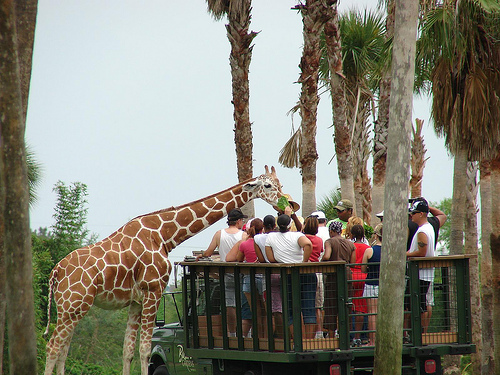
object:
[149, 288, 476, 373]
truck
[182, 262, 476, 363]
back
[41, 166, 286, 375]
giraffe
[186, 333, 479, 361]
platform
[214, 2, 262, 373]
trees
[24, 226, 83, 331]
brush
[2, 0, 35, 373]
tree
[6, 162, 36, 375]
trunk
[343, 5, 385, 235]
tree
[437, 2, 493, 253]
tree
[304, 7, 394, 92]
palm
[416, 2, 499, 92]
palm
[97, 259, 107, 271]
spots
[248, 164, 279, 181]
top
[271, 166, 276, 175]
ossicone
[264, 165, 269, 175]
ossicones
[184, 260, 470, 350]
fence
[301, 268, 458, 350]
grid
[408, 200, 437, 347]
man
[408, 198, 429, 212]
cap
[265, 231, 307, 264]
shirt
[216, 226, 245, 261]
shirt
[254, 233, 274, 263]
shirt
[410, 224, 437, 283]
shirt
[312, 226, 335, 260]
shirt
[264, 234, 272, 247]
sleeves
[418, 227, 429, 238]
sleeves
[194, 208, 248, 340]
people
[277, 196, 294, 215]
food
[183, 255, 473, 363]
wagon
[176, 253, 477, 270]
railing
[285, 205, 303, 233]
person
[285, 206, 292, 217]
hand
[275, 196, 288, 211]
leaf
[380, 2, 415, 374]
tree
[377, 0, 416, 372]
bark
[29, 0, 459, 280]
sky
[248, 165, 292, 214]
head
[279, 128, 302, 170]
leaf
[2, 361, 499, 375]
down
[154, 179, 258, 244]
neck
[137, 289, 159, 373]
legs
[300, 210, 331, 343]
person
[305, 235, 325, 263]
shirt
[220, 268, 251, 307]
shorts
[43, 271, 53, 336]
tail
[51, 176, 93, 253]
tree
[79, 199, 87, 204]
leaves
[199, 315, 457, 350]
deck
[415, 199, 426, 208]
color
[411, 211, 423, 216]
sunglasses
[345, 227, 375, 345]
woman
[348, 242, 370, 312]
outfit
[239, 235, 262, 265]
shirt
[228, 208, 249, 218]
cap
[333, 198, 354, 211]
cap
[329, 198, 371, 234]
man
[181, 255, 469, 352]
cage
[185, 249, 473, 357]
safety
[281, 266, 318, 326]
capris